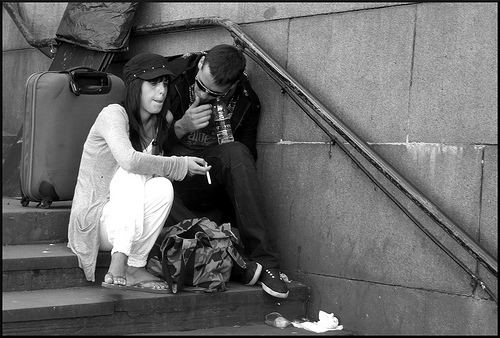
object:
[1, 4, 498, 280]
handrail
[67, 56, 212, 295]
woman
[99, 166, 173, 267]
pants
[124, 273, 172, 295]
flip flops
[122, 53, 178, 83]
hat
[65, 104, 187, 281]
jacket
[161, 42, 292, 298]
man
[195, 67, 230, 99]
sunglasses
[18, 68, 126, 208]
suitcase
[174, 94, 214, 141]
hand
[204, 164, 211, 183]
cigarette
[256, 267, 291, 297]
shoes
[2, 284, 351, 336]
steps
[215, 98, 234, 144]
bottle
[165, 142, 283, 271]
pants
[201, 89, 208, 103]
nose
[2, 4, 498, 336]
wall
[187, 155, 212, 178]
hand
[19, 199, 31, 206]
wheel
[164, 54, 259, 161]
jacket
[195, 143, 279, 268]
leg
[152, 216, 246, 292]
bag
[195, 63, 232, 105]
face